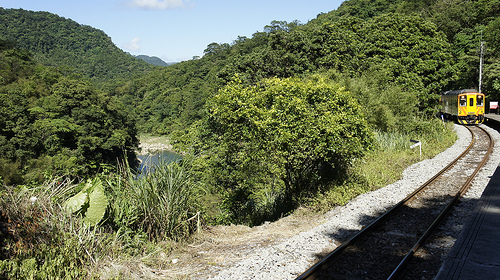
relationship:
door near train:
[467, 95, 476, 112] [439, 87, 487, 127]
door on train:
[467, 95, 476, 112] [428, 84, 496, 122]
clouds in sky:
[123, 0, 195, 65] [2, 2, 343, 62]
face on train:
[453, 85, 493, 125] [437, 87, 483, 124]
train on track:
[432, 88, 486, 127] [335, 120, 480, 277]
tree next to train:
[172, 76, 289, 220] [406, 65, 491, 153]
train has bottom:
[432, 88, 486, 127] [464, 118, 480, 128]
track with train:
[388, 163, 482, 275] [437, 84, 498, 139]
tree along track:
[172, 76, 289, 220] [460, 122, 495, 211]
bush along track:
[0, 159, 217, 278] [406, 146, 463, 240]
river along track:
[135, 145, 184, 185] [388, 163, 482, 275]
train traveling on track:
[432, 88, 488, 125] [388, 163, 482, 275]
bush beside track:
[0, 159, 217, 278] [388, 163, 482, 275]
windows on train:
[458, 94, 484, 107] [440, 90, 484, 122]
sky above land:
[2, 2, 343, 62] [1, 112, 499, 279]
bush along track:
[3, 68, 140, 185] [390, 128, 497, 278]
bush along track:
[0, 159, 217, 278] [390, 128, 497, 278]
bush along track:
[0, 159, 217, 278] [412, 108, 497, 273]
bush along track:
[0, 159, 217, 278] [388, 163, 482, 275]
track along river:
[388, 163, 482, 275] [135, 145, 184, 185]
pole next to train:
[476, 44, 483, 91] [438, 85, 491, 127]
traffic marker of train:
[401, 128, 428, 165] [435, 84, 495, 135]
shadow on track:
[297, 184, 499, 278] [388, 163, 482, 275]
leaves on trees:
[370, 24, 440, 87] [1, 1, 498, 192]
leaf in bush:
[208, 86, 318, 173] [0, 159, 217, 278]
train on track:
[432, 88, 486, 127] [388, 163, 482, 275]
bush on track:
[0, 159, 217, 278] [388, 163, 482, 275]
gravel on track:
[211, 122, 498, 278] [388, 163, 482, 275]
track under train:
[388, 163, 482, 275] [432, 88, 486, 127]